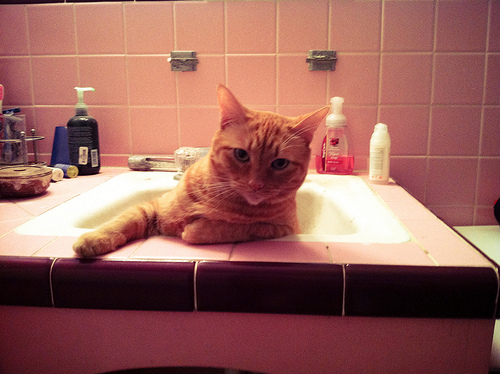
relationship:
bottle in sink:
[65, 85, 100, 176] [28, 87, 496, 313]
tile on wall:
[123, 98, 178, 154] [1, 3, 467, 172]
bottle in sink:
[65, 85, 100, 176] [17, 163, 414, 245]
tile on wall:
[425, 54, 495, 181] [2, 3, 497, 226]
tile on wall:
[375, 43, 436, 111] [2, 3, 497, 226]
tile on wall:
[219, 47, 281, 110] [2, 3, 497, 226]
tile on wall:
[127, 98, 177, 154] [2, 3, 497, 226]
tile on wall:
[22, 3, 80, 57] [2, 3, 497, 226]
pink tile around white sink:
[3, 234, 493, 264] [17, 169, 412, 245]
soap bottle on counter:
[313, 86, 358, 180] [5, 161, 497, 268]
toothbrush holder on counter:
[1, 104, 49, 166] [0, 130, 500, 287]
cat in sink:
[139, 91, 339, 238] [86, 175, 354, 235]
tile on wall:
[377, 2, 441, 57] [2, 3, 497, 226]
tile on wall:
[373, 96, 436, 161] [2, 3, 497, 226]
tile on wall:
[119, 47, 183, 112] [2, 3, 497, 226]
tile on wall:
[24, 46, 82, 111] [2, 3, 497, 226]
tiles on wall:
[209, 12, 284, 82] [178, 10, 369, 110]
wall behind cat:
[178, 10, 369, 110] [173, 92, 318, 237]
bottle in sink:
[65, 85, 100, 176] [94, 154, 389, 261]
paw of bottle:
[70, 218, 112, 259] [65, 85, 100, 176]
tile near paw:
[0, 253, 54, 306] [70, 218, 112, 259]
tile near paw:
[52, 257, 194, 313] [70, 218, 112, 259]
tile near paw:
[195, 259, 343, 315] [70, 218, 112, 259]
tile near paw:
[342, 262, 499, 321] [70, 218, 112, 259]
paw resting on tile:
[62, 218, 131, 270] [383, 209, 451, 276]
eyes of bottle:
[224, 140, 299, 175] [65, 85, 100, 176]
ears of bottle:
[195, 69, 344, 141] [65, 85, 100, 176]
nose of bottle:
[240, 180, 267, 204] [65, 85, 100, 176]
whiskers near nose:
[180, 172, 238, 202] [240, 161, 270, 199]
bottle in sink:
[65, 85, 100, 176] [48, 156, 438, 272]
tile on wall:
[324, 46, 384, 109] [2, 3, 497, 226]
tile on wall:
[73, 48, 132, 108] [2, 3, 497, 226]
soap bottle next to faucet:
[313, 86, 358, 180] [137, 142, 201, 178]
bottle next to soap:
[367, 120, 391, 188] [358, 96, 431, 202]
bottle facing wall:
[65, 85, 102, 176] [2, 3, 497, 226]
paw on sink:
[70, 218, 112, 259] [6, 167, 483, 271]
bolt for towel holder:
[166, 57, 177, 64] [167, 49, 338, 77]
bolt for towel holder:
[188, 59, 198, 66] [167, 49, 338, 77]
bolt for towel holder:
[301, 57, 315, 64] [167, 49, 338, 77]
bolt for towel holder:
[326, 57, 337, 61] [167, 49, 338, 77]